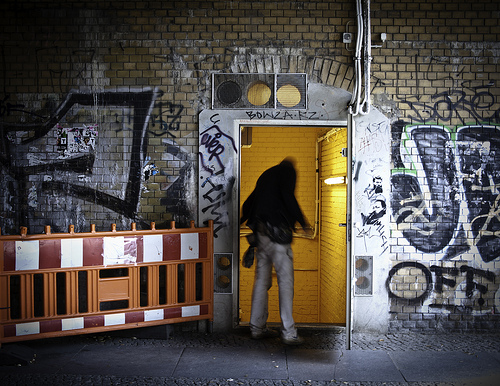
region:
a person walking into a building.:
[216, 144, 328, 349]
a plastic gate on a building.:
[0, 211, 224, 361]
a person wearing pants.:
[241, 230, 301, 348]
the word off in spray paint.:
[381, 254, 497, 304]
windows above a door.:
[198, 60, 325, 140]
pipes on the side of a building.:
[350, 0, 377, 122]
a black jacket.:
[229, 170, 314, 244]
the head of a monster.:
[258, 136, 309, 193]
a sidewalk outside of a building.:
[0, 331, 495, 383]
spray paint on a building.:
[4, 61, 179, 222]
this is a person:
[246, 157, 318, 343]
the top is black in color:
[268, 180, 295, 228]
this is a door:
[245, 130, 346, 321]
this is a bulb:
[311, 172, 353, 189]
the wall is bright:
[322, 209, 337, 278]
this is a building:
[116, 27, 454, 339]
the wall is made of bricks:
[180, 28, 245, 39]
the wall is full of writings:
[396, 128, 497, 279]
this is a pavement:
[349, 343, 451, 380]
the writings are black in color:
[414, 235, 436, 245]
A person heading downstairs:
[252, 150, 297, 293]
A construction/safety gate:
[12, 222, 217, 336]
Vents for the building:
[195, 58, 311, 113]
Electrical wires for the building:
[332, 9, 387, 126]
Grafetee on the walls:
[33, 81, 168, 206]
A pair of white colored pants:
[239, 224, 295, 349]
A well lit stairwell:
[248, 127, 354, 291]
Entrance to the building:
[218, 116, 363, 335]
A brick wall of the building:
[23, 18, 128, 69]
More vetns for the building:
[347, 246, 371, 298]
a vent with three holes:
[206, 65, 311, 113]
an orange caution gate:
[10, 230, 208, 333]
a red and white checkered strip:
[9, 237, 211, 264]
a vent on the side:
[354, 252, 379, 294]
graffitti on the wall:
[391, 90, 497, 328]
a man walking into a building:
[249, 151, 316, 359]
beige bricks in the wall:
[199, 15, 323, 37]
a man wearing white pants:
[243, 162, 312, 349]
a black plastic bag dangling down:
[241, 231, 257, 266]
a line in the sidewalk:
[163, 346, 200, 378]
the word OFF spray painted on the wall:
[382, 259, 495, 320]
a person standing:
[242, 155, 313, 341]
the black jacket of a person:
[239, 169, 314, 234]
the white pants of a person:
[253, 235, 305, 334]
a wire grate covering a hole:
[212, 251, 232, 291]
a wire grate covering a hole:
[347, 255, 374, 295]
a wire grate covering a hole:
[210, 73, 310, 108]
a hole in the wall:
[355, 278, 369, 288]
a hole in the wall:
[355, 257, 370, 270]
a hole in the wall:
[217, 275, 228, 287]